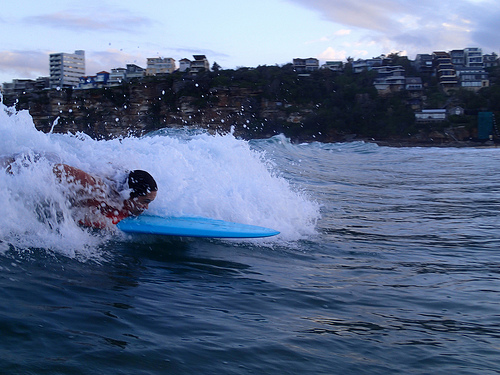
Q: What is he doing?
A: He is surfing.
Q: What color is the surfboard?
A: It is blue.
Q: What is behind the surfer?
A: There are buildings behind the surfer.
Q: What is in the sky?
A: Clouds are in the sky.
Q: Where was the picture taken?
A: Outside.